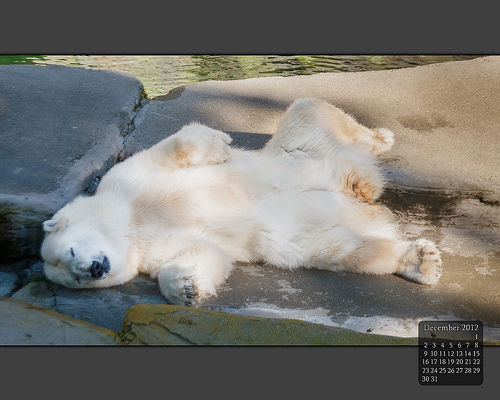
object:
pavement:
[7, 174, 498, 346]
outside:
[0, 53, 500, 348]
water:
[149, 55, 179, 80]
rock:
[117, 55, 500, 211]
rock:
[0, 63, 146, 273]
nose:
[90, 260, 105, 279]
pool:
[44, 54, 384, 98]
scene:
[0, 53, 499, 348]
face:
[40, 234, 99, 289]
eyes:
[69, 247, 82, 285]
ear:
[42, 219, 61, 232]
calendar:
[418, 320, 483, 387]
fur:
[112, 167, 354, 253]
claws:
[183, 286, 195, 307]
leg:
[262, 97, 395, 163]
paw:
[179, 121, 232, 165]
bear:
[40, 96, 442, 308]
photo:
[0, 0, 500, 400]